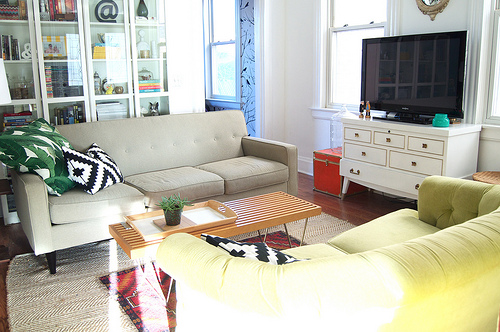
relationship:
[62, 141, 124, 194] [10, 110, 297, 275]
pillow on couch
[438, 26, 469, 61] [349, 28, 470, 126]
corner of television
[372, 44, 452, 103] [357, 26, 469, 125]
reflection in television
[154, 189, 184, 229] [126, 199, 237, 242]
plant on tray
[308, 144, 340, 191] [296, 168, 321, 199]
red chest on floor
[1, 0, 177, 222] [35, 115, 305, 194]
bookshelf behind sofa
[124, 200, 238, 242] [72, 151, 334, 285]
tray on table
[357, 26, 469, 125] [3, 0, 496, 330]
television in room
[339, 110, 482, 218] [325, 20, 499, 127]
drawers under television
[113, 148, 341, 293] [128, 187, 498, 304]
table in front of couch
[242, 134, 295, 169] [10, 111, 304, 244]
arm of couch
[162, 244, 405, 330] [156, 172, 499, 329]
light hitting couch